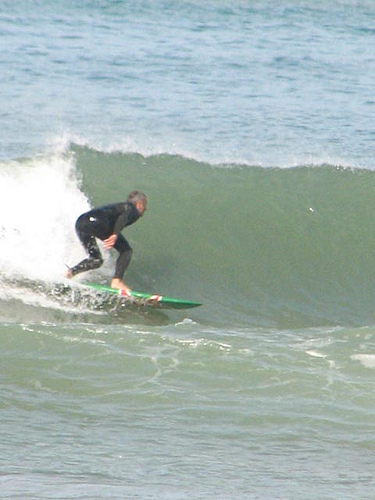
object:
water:
[0, 148, 374, 329]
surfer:
[62, 188, 149, 295]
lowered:
[74, 202, 140, 244]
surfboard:
[54, 270, 205, 313]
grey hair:
[126, 190, 147, 206]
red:
[155, 295, 159, 301]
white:
[149, 295, 156, 300]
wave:
[70, 146, 374, 327]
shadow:
[1, 299, 172, 328]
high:
[40, 137, 373, 198]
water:
[0, 323, 375, 500]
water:
[0, 0, 375, 150]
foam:
[0, 152, 117, 314]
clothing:
[68, 201, 141, 281]